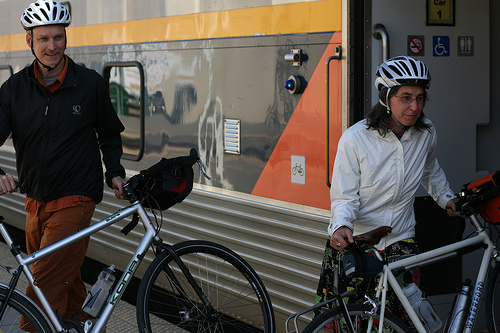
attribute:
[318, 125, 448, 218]
jacket — white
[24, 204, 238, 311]
bike — silver, green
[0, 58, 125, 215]
shirt — orange, cotton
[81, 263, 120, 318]
bottle — plastic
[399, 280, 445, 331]
bottle — plastic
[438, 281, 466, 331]
bottle — plastic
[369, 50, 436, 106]
helmet — white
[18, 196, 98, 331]
pants — orange, cotton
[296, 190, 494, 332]
bike — silver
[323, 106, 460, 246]
jacket — white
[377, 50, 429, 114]
helmet — silver, black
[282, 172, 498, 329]
bike — white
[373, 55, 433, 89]
cycling helmet — black, white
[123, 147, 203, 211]
bag — black, red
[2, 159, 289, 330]
bike — silver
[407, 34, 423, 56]
sign — no smoking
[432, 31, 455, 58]
handicap sign — blue, white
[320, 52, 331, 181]
bar — metal